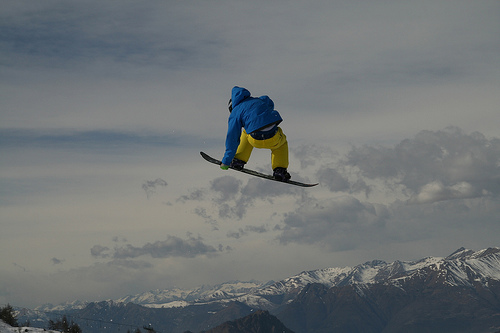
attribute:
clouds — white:
[135, 129, 495, 236]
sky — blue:
[0, 4, 492, 244]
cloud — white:
[215, 24, 495, 109]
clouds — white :
[302, 53, 499, 211]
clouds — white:
[387, 98, 490, 125]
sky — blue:
[7, 123, 195, 245]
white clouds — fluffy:
[95, 33, 180, 68]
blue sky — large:
[0, 5, 499, 305]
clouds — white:
[8, 3, 498, 263]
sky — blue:
[0, 2, 498, 302]